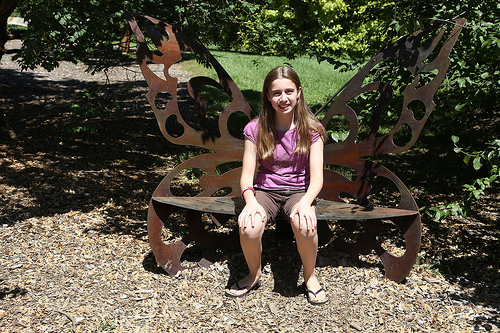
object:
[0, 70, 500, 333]
shadow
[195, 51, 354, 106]
grass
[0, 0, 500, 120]
tree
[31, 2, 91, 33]
branch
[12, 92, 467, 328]
leaves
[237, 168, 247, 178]
elbow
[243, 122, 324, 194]
tee shirt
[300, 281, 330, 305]
flip flops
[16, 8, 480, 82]
leaves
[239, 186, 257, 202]
wrist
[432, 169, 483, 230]
branch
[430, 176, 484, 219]
leaves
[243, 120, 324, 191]
blouse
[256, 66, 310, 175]
hair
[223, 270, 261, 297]
feet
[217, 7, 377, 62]
leaves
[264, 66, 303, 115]
head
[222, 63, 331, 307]
girl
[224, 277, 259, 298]
flip flops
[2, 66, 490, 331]
shadows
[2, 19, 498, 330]
ground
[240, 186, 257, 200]
bracelet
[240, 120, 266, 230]
arm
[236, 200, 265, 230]
hands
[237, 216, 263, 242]
knees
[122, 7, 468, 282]
butterfly bench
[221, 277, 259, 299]
slipper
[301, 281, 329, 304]
slipper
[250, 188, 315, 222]
shorts